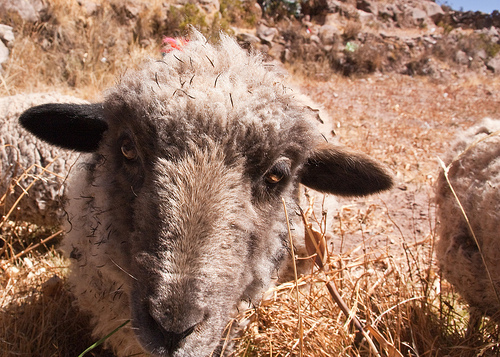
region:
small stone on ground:
[398, 177, 408, 194]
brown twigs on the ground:
[308, 268, 374, 315]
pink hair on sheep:
[163, 28, 193, 59]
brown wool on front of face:
[150, 181, 260, 247]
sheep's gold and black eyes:
[245, 141, 312, 212]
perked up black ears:
[15, 86, 136, 145]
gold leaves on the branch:
[288, 220, 344, 267]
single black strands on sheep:
[163, 49, 218, 99]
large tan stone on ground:
[0, 14, 39, 66]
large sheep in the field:
[40, 33, 396, 323]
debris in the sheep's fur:
[98, 37, 355, 152]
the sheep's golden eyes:
[98, 88, 309, 203]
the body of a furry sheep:
[417, 91, 499, 298]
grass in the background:
[308, 23, 488, 96]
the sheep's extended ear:
[278, 104, 408, 226]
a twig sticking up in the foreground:
[299, 236, 383, 356]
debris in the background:
[286, 9, 388, 64]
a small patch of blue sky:
[423, 0, 498, 43]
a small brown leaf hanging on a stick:
[292, 208, 341, 270]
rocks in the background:
[7, 0, 342, 49]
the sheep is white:
[77, 83, 324, 318]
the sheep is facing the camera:
[72, 105, 342, 287]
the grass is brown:
[344, 271, 424, 333]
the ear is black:
[16, 98, 114, 147]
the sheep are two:
[3, 95, 495, 328]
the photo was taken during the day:
[14, 12, 499, 308]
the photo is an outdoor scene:
[0, 110, 489, 346]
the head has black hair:
[157, 55, 238, 110]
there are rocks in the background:
[346, 7, 450, 42]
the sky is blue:
[460, 1, 496, 8]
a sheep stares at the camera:
[26, 91, 380, 353]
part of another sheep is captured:
[428, 112, 498, 354]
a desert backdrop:
[326, 3, 498, 123]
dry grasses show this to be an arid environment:
[326, 274, 463, 354]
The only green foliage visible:
[74, 310, 132, 355]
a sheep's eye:
[116, 131, 144, 163]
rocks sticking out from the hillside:
[241, 24, 499, 74]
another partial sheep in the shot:
[0, 72, 63, 229]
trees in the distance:
[447, 6, 499, 34]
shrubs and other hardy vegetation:
[2, 7, 279, 48]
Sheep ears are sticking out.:
[19, 87, 114, 153]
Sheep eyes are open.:
[109, 133, 343, 204]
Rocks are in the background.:
[315, 17, 467, 75]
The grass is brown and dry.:
[296, 256, 419, 356]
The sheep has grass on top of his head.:
[161, 38, 288, 107]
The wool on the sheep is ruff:
[137, 51, 257, 237]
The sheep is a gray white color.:
[105, 45, 310, 260]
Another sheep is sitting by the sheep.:
[252, 65, 492, 310]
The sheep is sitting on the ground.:
[17, 43, 384, 337]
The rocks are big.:
[319, 12, 453, 82]